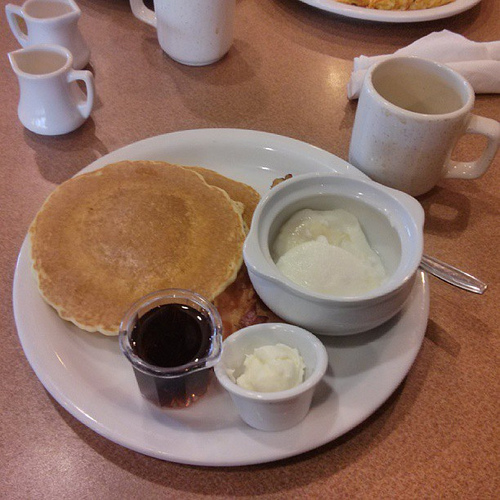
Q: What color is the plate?
A: White.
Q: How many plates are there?
A: One.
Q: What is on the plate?
A: Pancakes.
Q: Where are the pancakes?
A: On the plate.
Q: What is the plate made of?
A: Porcelain.